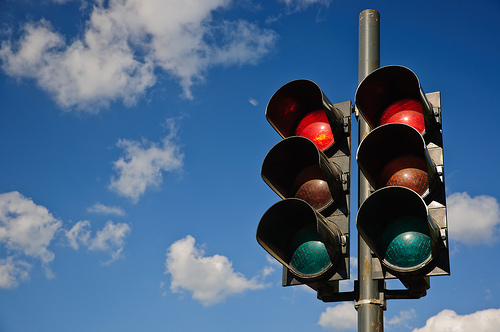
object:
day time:
[0, 0, 500, 332]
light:
[288, 239, 336, 274]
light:
[291, 176, 328, 205]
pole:
[355, 8, 385, 332]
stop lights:
[376, 99, 429, 136]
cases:
[357, 185, 437, 261]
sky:
[0, 0, 500, 332]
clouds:
[0, 0, 237, 119]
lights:
[386, 229, 432, 267]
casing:
[265, 78, 336, 140]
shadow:
[281, 100, 300, 117]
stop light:
[294, 112, 332, 151]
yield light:
[389, 163, 428, 195]